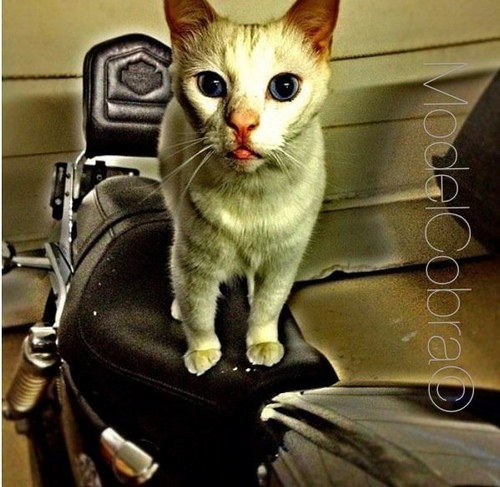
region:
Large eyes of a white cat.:
[194, 68, 303, 102]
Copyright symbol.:
[424, 363, 473, 410]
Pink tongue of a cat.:
[225, 148, 255, 162]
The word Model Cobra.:
[422, 60, 469, 366]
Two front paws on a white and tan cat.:
[178, 336, 286, 375]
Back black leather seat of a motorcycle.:
[81, 33, 181, 159]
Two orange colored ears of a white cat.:
[163, 0, 340, 55]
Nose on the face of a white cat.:
[227, 109, 258, 141]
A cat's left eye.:
[265, 71, 303, 101]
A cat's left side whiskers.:
[259, 140, 363, 203]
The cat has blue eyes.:
[180, 61, 315, 102]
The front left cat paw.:
[160, 320, 230, 377]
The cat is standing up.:
[160, 5, 315, 380]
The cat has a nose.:
[220, 100, 260, 130]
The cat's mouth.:
[215, 135, 275, 165]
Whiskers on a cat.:
[150, 110, 225, 205]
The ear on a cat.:
[270, 0, 354, 69]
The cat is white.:
[160, 5, 345, 395]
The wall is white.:
[370, 5, 440, 155]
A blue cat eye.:
[257, 65, 322, 111]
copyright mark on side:
[413, 50, 496, 427]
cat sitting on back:
[158, 0, 318, 380]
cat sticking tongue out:
[166, 1, 318, 188]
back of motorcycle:
[81, 40, 152, 165]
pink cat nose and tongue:
[223, 110, 266, 167]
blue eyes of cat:
[172, 65, 293, 107]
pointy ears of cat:
[161, 0, 346, 57]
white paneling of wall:
[343, 6, 415, 263]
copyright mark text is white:
[408, 44, 485, 336]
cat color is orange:
[143, 0, 298, 379]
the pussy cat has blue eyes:
[192, 63, 306, 106]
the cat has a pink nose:
[227, 110, 258, 137]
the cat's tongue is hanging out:
[219, 145, 265, 165]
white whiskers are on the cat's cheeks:
[131, 126, 362, 173]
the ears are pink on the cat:
[162, 2, 344, 58]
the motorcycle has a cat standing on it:
[8, 2, 491, 472]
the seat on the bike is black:
[60, 175, 338, 483]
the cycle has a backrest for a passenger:
[66, 31, 176, 199]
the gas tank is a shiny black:
[253, 379, 498, 483]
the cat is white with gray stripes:
[158, 0, 334, 374]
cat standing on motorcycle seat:
[144, 9, 389, 464]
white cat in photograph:
[114, 0, 321, 379]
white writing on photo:
[382, 31, 494, 371]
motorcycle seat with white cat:
[58, 26, 286, 480]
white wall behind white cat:
[7, 12, 463, 400]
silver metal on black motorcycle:
[1, 298, 226, 484]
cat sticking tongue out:
[202, 108, 307, 180]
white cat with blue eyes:
[172, 63, 323, 116]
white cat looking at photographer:
[136, 16, 368, 368]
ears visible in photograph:
[147, 3, 426, 45]